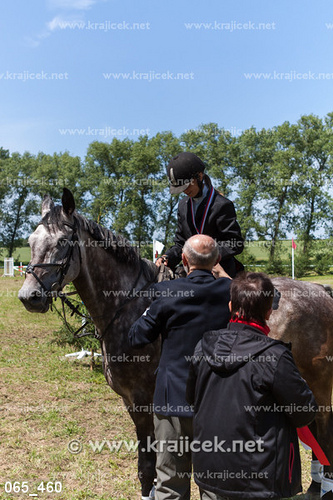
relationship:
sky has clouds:
[0, 0, 332, 242] [40, 3, 82, 29]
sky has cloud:
[1, 0, 332, 156] [19, 26, 51, 52]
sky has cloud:
[1, 0, 332, 156] [47, 11, 81, 32]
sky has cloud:
[1, 0, 332, 156] [41, 0, 98, 12]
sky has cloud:
[1, 0, 332, 156] [2, 119, 50, 152]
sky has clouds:
[0, 0, 332, 242] [25, 2, 100, 49]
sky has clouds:
[0, 0, 332, 242] [18, 10, 93, 59]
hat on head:
[166, 151, 205, 194] [167, 152, 209, 198]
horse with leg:
[56, 206, 314, 383] [302, 423, 329, 492]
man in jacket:
[191, 273, 316, 500] [189, 321, 310, 495]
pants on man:
[155, 402, 213, 499] [130, 230, 240, 497]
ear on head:
[39, 191, 53, 216] [16, 203, 101, 319]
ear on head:
[59, 185, 73, 217] [16, 203, 101, 319]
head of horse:
[16, 203, 101, 319] [24, 187, 332, 498]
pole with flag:
[285, 240, 296, 277] [289, 237, 299, 249]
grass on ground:
[303, 273, 330, 282] [1, 271, 331, 496]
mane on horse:
[71, 213, 146, 265] [16, 216, 332, 433]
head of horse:
[19, 188, 81, 314] [24, 187, 332, 498]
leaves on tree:
[275, 121, 295, 148] [229, 119, 306, 257]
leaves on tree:
[269, 147, 297, 177] [229, 119, 306, 257]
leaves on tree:
[256, 128, 277, 162] [229, 119, 306, 257]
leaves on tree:
[264, 178, 285, 198] [229, 119, 306, 257]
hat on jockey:
[166, 151, 205, 194] [150, 143, 247, 285]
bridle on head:
[23, 217, 79, 310] [19, 188, 81, 314]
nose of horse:
[17, 284, 44, 303] [24, 187, 332, 498]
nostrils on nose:
[30, 289, 42, 299] [17, 284, 44, 303]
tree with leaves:
[180, 118, 247, 233] [231, 126, 280, 233]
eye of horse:
[54, 232, 71, 251] [24, 187, 332, 498]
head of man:
[176, 224, 224, 269] [124, 234, 251, 497]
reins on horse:
[84, 254, 166, 338] [8, 164, 332, 457]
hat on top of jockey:
[165, 151, 206, 195] [155, 149, 249, 288]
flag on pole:
[288, 238, 294, 251] [285, 242, 298, 281]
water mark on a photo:
[0, 0, 333, 499] [0, 0, 332, 499]